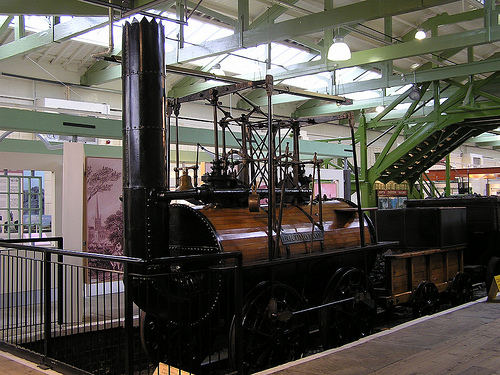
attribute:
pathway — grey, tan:
[394, 346, 429, 361]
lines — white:
[292, 349, 329, 364]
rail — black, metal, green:
[95, 252, 129, 262]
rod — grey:
[22, 251, 52, 294]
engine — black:
[250, 270, 334, 316]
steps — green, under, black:
[405, 136, 445, 157]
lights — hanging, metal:
[329, 44, 352, 57]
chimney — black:
[112, 21, 182, 202]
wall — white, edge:
[1, 76, 49, 98]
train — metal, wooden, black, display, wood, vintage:
[116, 194, 471, 314]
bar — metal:
[238, 37, 281, 51]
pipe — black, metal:
[120, 23, 160, 53]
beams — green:
[407, 22, 484, 118]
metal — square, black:
[118, 181, 166, 223]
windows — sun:
[134, 2, 277, 73]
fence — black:
[215, 109, 318, 163]